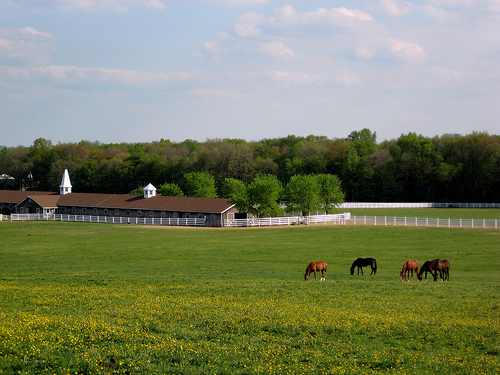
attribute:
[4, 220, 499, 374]
grass — large area, a field, green colored, soft, very green, dark green, long, big, yellowish, green, large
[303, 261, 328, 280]
horse — white striped, grazing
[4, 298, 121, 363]
flowers — yellow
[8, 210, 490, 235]
fence — wooden, white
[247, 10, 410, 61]
clouds — grayish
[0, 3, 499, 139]
sky — cloudy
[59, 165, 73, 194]
steeple — narrow, white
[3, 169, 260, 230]
house — large, brown, a stable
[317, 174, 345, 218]
tree — in back, in a row, bright green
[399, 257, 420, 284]
horse — grazing, light brown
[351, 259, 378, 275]
horse — black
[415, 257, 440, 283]
horse — dark brown